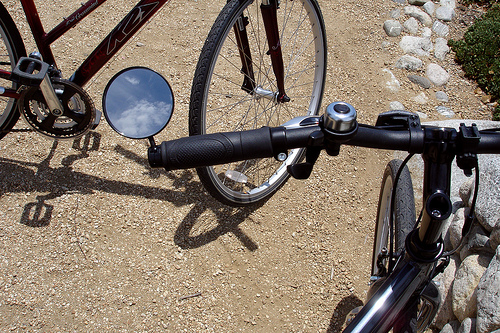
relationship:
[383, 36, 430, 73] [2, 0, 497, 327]
rock in back of bike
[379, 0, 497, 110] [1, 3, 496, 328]
rock in back of bikes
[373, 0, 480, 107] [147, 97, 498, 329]
rock in back of bike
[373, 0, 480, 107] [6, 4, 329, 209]
rock in back of bike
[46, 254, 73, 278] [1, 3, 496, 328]
rock in back of bikes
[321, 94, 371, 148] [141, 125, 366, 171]
bell attached to handlebars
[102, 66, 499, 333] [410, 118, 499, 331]
bicycle leaning on rocks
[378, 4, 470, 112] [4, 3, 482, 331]
rocks in dirt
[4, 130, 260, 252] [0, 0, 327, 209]
shadow behind bicycle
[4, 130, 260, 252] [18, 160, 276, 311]
shadow on ground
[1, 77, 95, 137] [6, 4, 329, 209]
chain on bike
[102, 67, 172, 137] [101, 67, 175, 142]
reflection in mirror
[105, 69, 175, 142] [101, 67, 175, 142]
sky in mirror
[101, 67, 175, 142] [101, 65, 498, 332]
mirror on bike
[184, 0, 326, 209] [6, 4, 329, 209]
tire on bike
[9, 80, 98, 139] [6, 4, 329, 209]
chain on bike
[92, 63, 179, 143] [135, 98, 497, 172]
mirror on handlebars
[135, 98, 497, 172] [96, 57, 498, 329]
handlebars on bicycle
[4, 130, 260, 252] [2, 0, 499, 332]
shadow on ground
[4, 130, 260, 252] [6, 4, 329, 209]
shadow behind bike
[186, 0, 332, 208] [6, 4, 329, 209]
tire on bike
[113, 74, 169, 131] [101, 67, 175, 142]
clouds in mirror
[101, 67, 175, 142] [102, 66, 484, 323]
mirror on bicycle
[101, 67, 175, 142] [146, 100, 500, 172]
mirror on handlebars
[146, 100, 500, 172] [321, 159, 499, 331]
handlebars on bike